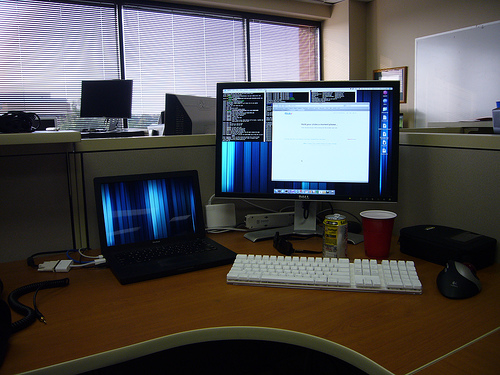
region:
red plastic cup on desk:
[352, 205, 399, 263]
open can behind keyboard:
[315, 208, 346, 263]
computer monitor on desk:
[209, 74, 404, 241]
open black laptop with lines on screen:
[87, 169, 237, 281]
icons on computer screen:
[376, 90, 395, 167]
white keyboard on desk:
[222, 244, 429, 300]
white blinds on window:
[12, 71, 77, 108]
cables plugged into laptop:
[41, 249, 103, 279]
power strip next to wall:
[229, 201, 302, 235]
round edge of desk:
[171, 315, 343, 356]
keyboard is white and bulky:
[223, 236, 478, 305]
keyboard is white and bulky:
[193, 199, 431, 359]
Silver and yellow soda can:
[318, 214, 354, 262]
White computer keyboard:
[226, 250, 424, 297]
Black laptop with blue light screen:
[87, 166, 239, 284]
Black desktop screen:
[78, 73, 137, 123]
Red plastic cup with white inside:
[355, 208, 400, 258]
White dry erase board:
[405, 37, 497, 135]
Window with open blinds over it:
[2, 5, 317, 116]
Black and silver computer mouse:
[436, 255, 478, 302]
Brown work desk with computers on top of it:
[17, 233, 485, 352]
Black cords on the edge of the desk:
[6, 274, 76, 342]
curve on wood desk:
[178, 309, 330, 352]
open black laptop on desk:
[89, 171, 235, 285]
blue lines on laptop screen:
[112, 188, 172, 231]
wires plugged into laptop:
[24, 240, 107, 278]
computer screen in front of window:
[76, 75, 136, 122]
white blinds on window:
[142, 67, 198, 84]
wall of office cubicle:
[411, 133, 473, 211]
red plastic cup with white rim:
[355, 205, 397, 261]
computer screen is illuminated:
[206, 76, 427, 244]